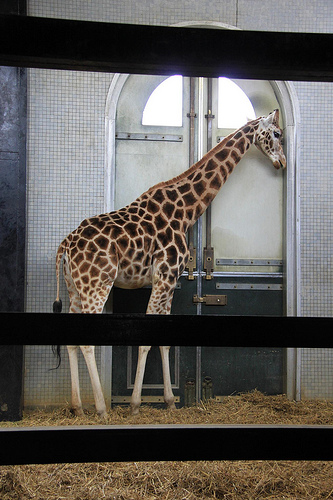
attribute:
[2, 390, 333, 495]
hay — brown, yellow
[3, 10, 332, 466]
fence — black, dark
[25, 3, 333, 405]
wall — white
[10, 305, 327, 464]
fence — black, wooden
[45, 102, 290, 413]
giraffe — tall, standing, brown, yellow, long, spotted, waiting, sad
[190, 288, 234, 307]
door latch — brown, wooden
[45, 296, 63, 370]
tip — black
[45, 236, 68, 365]
tail — giraffe's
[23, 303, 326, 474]
fence — in foreground